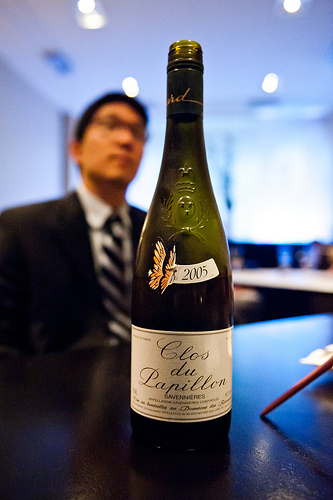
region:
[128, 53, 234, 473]
wine bottle on table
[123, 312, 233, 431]
label on wine bottle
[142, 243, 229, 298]
label on wine bottle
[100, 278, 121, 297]
stripe on the tie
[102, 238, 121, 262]
stripe on the tie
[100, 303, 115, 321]
stripe on the tie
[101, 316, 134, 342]
stripe on the tie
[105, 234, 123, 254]
stripe on the tie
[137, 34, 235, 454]
Bottle of wine on the table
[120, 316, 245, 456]
Bottle of wine on the table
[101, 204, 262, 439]
Bottle of wine on the table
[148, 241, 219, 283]
year 2005 on a bottle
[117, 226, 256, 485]
green bottle on a table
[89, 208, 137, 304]
man wearing a tie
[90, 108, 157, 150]
man wearing black glasses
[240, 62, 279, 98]
lights on the ceiling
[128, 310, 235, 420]
labels on a bottle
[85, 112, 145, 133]
glasses on the man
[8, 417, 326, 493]
table in front of man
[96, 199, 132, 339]
tie on the man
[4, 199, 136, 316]
suit on the person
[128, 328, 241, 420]
a label with lettering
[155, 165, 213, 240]
imprint of a pattern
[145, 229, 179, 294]
image of an insect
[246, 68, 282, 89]
light on the ceiling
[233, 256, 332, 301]
table behind the man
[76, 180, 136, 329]
shirt under man's jacket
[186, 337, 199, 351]
black letter on bottle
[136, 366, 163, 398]
black letter on bottle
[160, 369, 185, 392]
black letter on bottle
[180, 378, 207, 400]
black letter on bottle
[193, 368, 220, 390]
black letter on bottle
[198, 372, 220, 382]
black letter on bottle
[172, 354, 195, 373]
black letter on bottle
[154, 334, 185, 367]
black letter on bottle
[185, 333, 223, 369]
black letter on bottle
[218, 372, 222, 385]
black letter on bottle